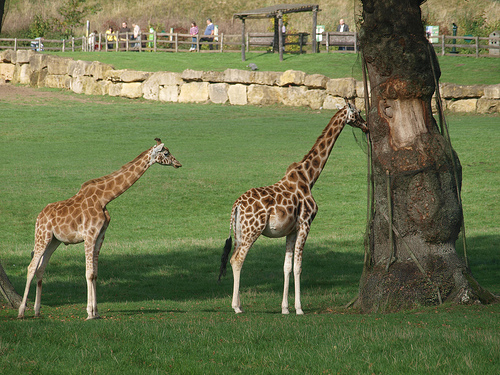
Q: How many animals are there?
A: Two.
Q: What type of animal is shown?
A: Giraffes.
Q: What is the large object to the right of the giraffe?
A: Tree.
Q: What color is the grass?
A: Green.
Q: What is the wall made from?
A: Stones.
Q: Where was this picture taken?
A: Zoo.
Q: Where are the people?
A: Behind the fence.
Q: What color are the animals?
A: Brown and white.